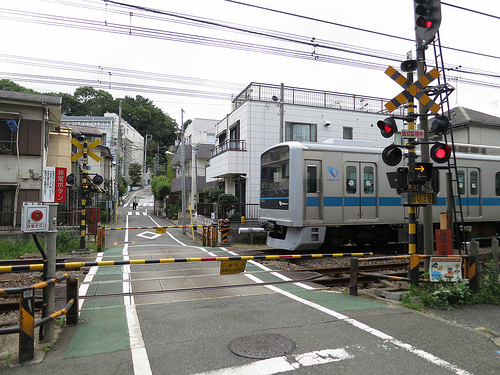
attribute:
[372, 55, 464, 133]
crossing sign — yellow, gray